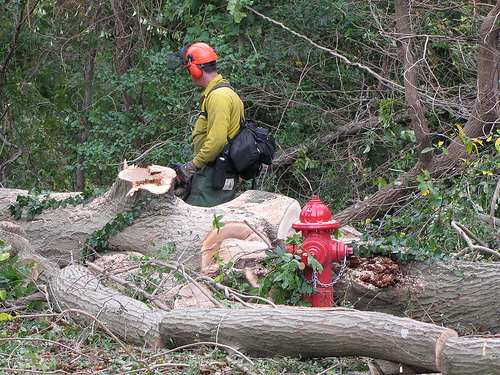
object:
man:
[173, 42, 246, 208]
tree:
[0, 156, 499, 372]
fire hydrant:
[283, 194, 353, 307]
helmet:
[181, 42, 219, 69]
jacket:
[191, 73, 247, 169]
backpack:
[224, 116, 279, 180]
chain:
[299, 245, 347, 288]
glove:
[173, 160, 197, 195]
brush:
[0, 0, 498, 260]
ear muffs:
[188, 64, 203, 79]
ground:
[0, 169, 499, 375]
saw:
[162, 166, 189, 195]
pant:
[185, 159, 237, 207]